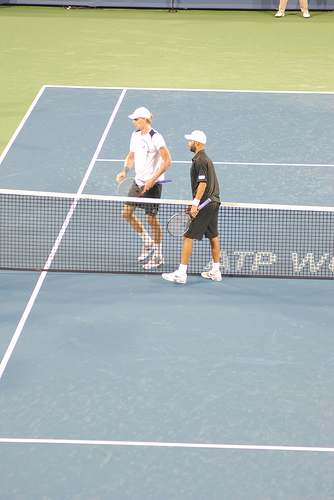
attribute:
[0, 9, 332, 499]
court — white , blue 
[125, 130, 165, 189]
shirt — white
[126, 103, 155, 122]
cap — white 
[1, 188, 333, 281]
net — black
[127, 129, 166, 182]
shirt — white , purple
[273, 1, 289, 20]
leg — set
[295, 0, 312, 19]
leg — set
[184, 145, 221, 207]
shirt — black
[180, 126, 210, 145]
hat — white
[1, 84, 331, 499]
court — blue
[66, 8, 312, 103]
area — green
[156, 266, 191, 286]
tennis shoe — white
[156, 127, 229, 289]
tennis player — standing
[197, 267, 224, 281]
tennis shoe — white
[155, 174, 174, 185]
handle — blue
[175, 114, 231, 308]
men — standing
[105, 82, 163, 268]
men — standing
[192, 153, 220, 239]
black — outfit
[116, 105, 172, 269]
player — male 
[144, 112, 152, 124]
hair — blonde 